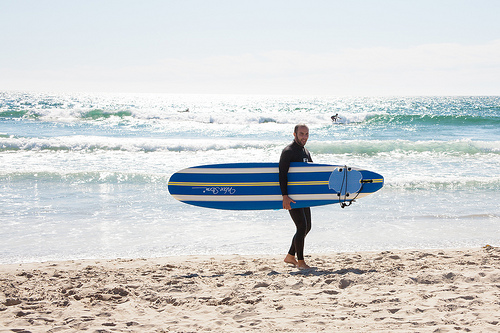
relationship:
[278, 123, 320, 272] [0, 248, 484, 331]
guy on beach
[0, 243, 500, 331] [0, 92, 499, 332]
sand on beach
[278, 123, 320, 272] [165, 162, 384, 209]
guy holding board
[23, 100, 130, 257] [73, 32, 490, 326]
water of ocean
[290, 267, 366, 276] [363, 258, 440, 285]
shadow in sand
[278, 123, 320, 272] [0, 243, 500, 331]
guy in sand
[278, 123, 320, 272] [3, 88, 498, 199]
guy near water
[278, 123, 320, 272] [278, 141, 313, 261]
guy wearing wet suit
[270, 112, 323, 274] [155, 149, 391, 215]
guy carrying surfboard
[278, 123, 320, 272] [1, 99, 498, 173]
guy near ocean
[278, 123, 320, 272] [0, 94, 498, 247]
guy near ocean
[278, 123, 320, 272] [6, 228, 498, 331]
guy near beach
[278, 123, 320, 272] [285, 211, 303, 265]
guy has leg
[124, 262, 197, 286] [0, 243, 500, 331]
foot marks are in sand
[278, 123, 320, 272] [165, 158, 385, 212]
guy carrying a surf board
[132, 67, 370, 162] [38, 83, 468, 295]
waves are in water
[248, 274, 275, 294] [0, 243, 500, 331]
track in sand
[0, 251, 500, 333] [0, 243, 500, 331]
track in sand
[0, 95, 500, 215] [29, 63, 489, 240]
waves are in ocean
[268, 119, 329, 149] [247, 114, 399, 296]
head attached to man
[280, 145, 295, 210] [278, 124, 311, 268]
arm attached to man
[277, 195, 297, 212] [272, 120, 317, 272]
hand attached to man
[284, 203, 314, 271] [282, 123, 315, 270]
legs are attached to man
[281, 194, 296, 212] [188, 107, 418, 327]
fingers are attached to man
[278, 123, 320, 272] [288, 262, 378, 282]
guy casting shadow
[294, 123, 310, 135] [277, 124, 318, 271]
dark hair attached to man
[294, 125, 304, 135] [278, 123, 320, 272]
dark hair attached to guy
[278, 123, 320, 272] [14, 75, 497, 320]
guy walking on beach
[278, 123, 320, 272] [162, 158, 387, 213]
guy holding surfboard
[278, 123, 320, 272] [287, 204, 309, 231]
guy wearing wet suit